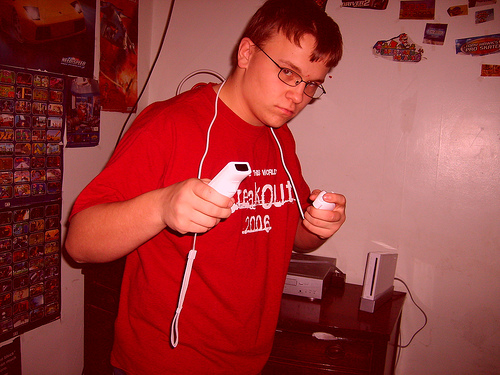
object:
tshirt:
[68, 82, 312, 375]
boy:
[63, 0, 346, 375]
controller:
[208, 162, 253, 198]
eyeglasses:
[254, 43, 326, 98]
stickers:
[341, 0, 500, 77]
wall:
[147, 0, 496, 375]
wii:
[358, 251, 401, 313]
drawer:
[270, 327, 386, 374]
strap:
[167, 249, 198, 350]